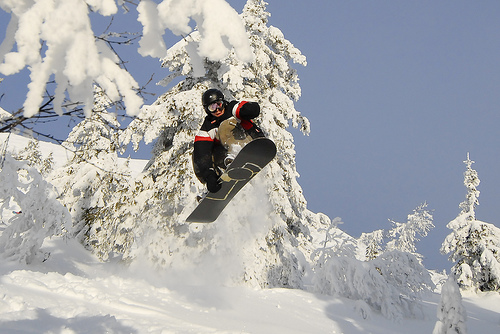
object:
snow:
[9, 260, 59, 297]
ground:
[304, 290, 422, 331]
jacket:
[192, 100, 262, 184]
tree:
[437, 149, 498, 293]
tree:
[118, 0, 315, 288]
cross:
[458, 149, 479, 174]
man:
[192, 87, 269, 193]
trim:
[232, 103, 242, 112]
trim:
[190, 129, 210, 141]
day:
[6, 2, 498, 329]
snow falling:
[155, 175, 283, 298]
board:
[186, 138, 280, 223]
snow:
[134, 284, 235, 319]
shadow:
[3, 300, 135, 332]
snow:
[248, 320, 268, 331]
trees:
[15, 1, 115, 90]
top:
[465, 169, 481, 212]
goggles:
[208, 99, 224, 112]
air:
[388, 33, 416, 43]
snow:
[106, 304, 148, 324]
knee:
[213, 118, 238, 136]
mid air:
[368, 98, 481, 173]